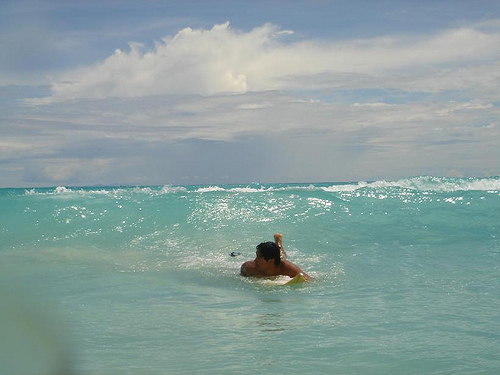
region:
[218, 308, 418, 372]
The water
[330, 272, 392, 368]
The water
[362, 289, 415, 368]
The water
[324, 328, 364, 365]
The water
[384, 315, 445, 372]
The water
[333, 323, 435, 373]
The water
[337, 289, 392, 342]
The water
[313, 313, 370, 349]
The water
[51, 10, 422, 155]
fluffy white clouds in the sky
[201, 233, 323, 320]
a man riding a surfboard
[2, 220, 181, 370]
light blue water in the ocean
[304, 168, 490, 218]
white capped waves in the ocean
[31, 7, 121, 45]
blue sky above the ocean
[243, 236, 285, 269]
a man's brown hair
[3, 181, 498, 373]
the big blue ocean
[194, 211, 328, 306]
a man on his belly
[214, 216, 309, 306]
a man lying down on a board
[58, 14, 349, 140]
a big white cloud in the sky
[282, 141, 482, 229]
white capped waves in the water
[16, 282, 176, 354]
calm green ocean water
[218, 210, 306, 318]
a man on a board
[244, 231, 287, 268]
a man with brown hair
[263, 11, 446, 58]
a blue sky with clouds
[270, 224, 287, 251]
a mans foot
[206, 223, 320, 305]
a man on his belly on a board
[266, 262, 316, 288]
the board under the man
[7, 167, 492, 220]
the deep blue ocean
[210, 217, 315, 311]
man on his belly in the ocean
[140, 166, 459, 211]
white capped waves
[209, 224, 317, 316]
man riding surfboard in ocean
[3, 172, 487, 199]
deep blue ocean water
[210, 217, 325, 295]
man in the ocean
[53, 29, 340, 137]
white clouds in the blue sky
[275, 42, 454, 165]
scattered clouds throughout the sky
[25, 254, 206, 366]
green blue water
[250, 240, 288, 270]
brown hair on the man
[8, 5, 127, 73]
blue sky between the clouds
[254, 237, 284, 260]
dark hair on a man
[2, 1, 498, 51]
blue sky above the clouds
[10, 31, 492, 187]
soft white clouds in the sky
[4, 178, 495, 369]
clear turquoise blue water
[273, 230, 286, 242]
a foot sticking out of the water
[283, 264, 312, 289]
an arm in the water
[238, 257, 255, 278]
a shoulder sticking out of the water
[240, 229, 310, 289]
a man swimming in the water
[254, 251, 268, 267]
a face on a man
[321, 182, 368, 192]
white top on a wave